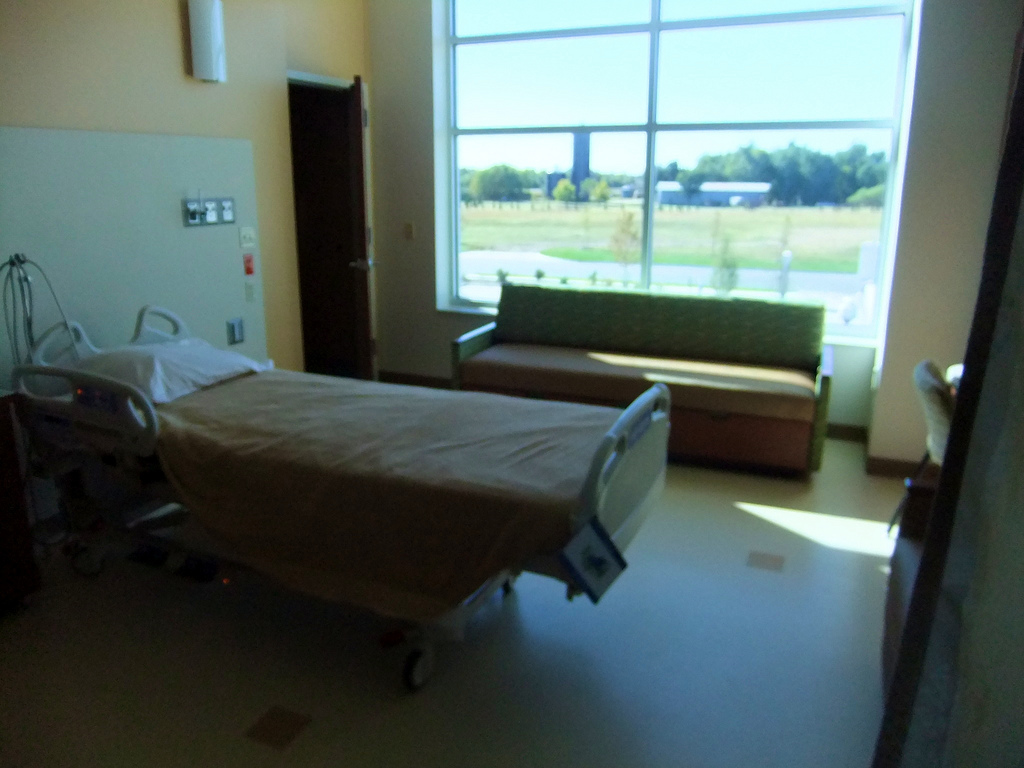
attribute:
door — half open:
[285, 69, 396, 409]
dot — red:
[208, 559, 241, 597]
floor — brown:
[6, 475, 926, 766]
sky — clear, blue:
[455, 4, 923, 125]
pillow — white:
[71, 307, 262, 415]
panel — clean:
[432, 0, 898, 373]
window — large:
[449, 0, 892, 375]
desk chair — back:
[917, 348, 960, 462]